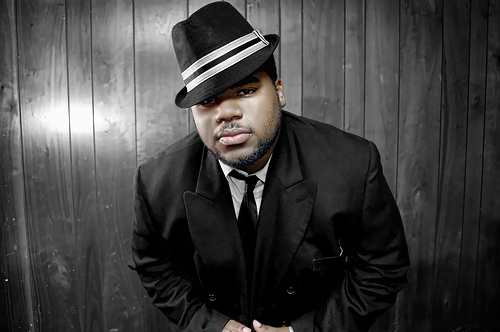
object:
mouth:
[216, 128, 253, 145]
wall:
[413, 93, 494, 319]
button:
[286, 287, 295, 295]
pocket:
[312, 245, 348, 271]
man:
[128, 1, 412, 332]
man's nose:
[214, 95, 243, 122]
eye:
[235, 85, 259, 96]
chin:
[216, 150, 268, 169]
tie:
[228, 169, 259, 274]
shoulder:
[131, 109, 380, 181]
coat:
[127, 109, 412, 332]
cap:
[171, 1, 281, 109]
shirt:
[217, 153, 273, 221]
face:
[191, 72, 282, 169]